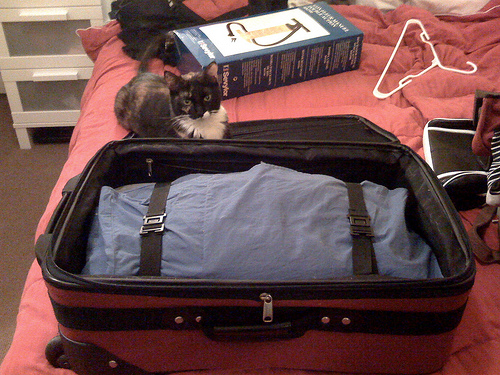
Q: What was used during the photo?
A: A telephoto lens.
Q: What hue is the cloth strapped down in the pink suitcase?
A: Blue.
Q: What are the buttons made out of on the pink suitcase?
A: Metal.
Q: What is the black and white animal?
A: A cat.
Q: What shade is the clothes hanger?
A: White.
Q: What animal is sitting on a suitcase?
A: Cat.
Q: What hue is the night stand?
A: White.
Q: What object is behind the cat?
A: A box.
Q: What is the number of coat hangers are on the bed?
A: One.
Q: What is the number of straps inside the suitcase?
A: Two.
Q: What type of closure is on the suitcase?
A: Zipper.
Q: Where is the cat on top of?
A: Bed.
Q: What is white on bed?
A: Hanger.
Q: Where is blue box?
A: Behind cat.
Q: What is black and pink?
A: Suitcase.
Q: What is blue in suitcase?
A: Clothing.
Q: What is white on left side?
A: Dresser.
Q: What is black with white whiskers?
A: Cat.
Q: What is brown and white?
A: Bag.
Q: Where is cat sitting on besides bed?
A: Suitcase top.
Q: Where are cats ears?
A: On head.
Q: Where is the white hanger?
A: On the bed.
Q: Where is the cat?
A: On the suitcase.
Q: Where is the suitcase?
A: On the bed.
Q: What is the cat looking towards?
A: The camera.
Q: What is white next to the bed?
A: A nightstand.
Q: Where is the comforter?
A: On the bed.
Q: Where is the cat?
A: On the bed.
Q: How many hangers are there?
A: One.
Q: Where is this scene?
A: In a bedroom.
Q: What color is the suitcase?
A: Red.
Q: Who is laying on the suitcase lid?
A: The cat.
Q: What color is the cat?
A: White, brown, and black.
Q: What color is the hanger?
A: White.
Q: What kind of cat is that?
A: Calico.